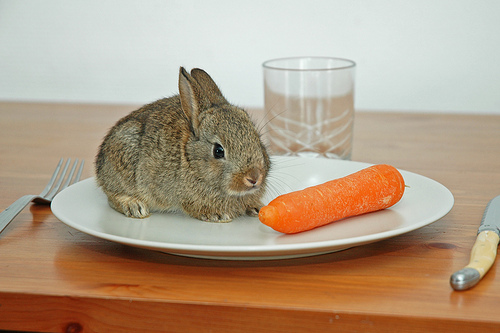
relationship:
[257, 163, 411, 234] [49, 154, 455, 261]
carrot on plate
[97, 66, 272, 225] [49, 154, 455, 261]
bunny on plate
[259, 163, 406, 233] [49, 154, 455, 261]
carrot on plate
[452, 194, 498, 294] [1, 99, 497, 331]
knife on table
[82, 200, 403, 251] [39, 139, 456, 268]
shadow on plate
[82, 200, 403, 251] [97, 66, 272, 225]
shadow from bunny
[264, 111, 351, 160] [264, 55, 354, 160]
etching on glass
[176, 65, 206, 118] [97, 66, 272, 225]
ear on bunny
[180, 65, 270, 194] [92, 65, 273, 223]
head of bunny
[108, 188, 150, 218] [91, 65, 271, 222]
leg of rabbit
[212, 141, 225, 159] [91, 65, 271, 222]
eye of rabbit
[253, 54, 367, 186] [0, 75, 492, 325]
glass on table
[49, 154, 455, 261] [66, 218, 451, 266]
plate has shadow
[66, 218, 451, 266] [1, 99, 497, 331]
shadow on table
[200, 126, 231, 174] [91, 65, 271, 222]
eye on rabbit